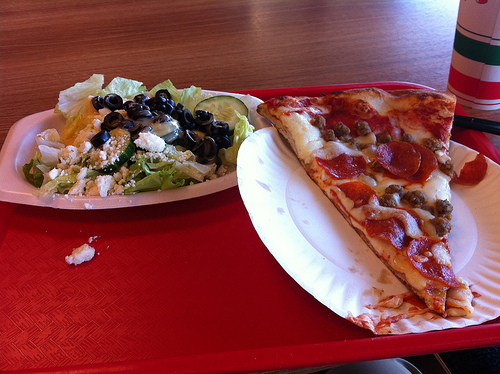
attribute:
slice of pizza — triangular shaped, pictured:
[256, 87, 475, 322]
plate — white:
[236, 127, 498, 336]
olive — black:
[106, 91, 123, 112]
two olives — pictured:
[92, 113, 123, 146]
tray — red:
[3, 80, 500, 374]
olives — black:
[89, 91, 234, 159]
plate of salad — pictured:
[1, 73, 276, 216]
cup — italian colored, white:
[445, 2, 499, 113]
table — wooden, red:
[1, 1, 499, 153]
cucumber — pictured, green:
[191, 92, 249, 122]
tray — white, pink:
[1, 86, 276, 213]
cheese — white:
[134, 130, 166, 156]